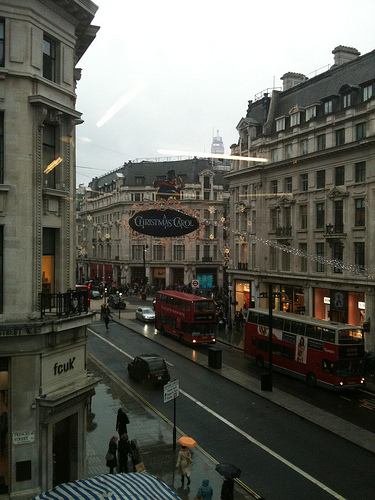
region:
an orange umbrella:
[175, 434, 196, 447]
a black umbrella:
[212, 459, 244, 479]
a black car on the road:
[125, 349, 173, 389]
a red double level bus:
[154, 286, 222, 350]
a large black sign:
[121, 197, 201, 248]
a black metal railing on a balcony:
[38, 284, 91, 318]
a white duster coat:
[173, 443, 192, 479]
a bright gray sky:
[72, 0, 374, 189]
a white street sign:
[160, 377, 179, 405]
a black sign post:
[170, 394, 177, 453]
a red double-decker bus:
[148, 287, 217, 348]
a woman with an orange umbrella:
[170, 430, 202, 491]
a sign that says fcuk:
[46, 355, 87, 381]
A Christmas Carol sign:
[124, 167, 209, 261]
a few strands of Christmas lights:
[222, 225, 366, 275]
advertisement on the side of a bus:
[254, 321, 324, 366]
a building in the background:
[88, 160, 218, 299]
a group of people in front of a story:
[92, 271, 223, 302]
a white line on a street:
[185, 395, 290, 465]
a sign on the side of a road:
[160, 378, 186, 405]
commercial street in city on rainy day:
[31, 155, 361, 458]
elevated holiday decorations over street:
[75, 171, 352, 297]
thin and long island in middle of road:
[105, 293, 349, 458]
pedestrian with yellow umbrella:
[142, 407, 202, 486]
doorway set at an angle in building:
[25, 375, 95, 490]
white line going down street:
[101, 326, 321, 484]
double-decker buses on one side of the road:
[141, 264, 363, 409]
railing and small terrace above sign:
[24, 204, 101, 386]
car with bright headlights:
[125, 285, 160, 336]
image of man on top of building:
[141, 157, 201, 217]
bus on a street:
[148, 283, 227, 351]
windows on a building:
[265, 196, 331, 239]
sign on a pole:
[156, 375, 182, 437]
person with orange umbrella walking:
[171, 433, 201, 491]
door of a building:
[45, 405, 87, 495]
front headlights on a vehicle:
[187, 336, 221, 345]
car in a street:
[120, 346, 175, 391]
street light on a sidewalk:
[112, 284, 128, 329]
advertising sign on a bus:
[288, 330, 311, 369]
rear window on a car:
[144, 357, 168, 373]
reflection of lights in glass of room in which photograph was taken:
[22, 67, 272, 193]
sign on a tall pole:
[156, 370, 182, 448]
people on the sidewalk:
[87, 373, 156, 472]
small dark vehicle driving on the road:
[111, 333, 171, 397]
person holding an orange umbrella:
[168, 426, 198, 478]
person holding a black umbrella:
[206, 456, 239, 497]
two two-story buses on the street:
[148, 285, 366, 406]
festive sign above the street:
[90, 176, 247, 395]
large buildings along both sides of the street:
[1, 0, 372, 480]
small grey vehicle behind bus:
[125, 300, 221, 348]